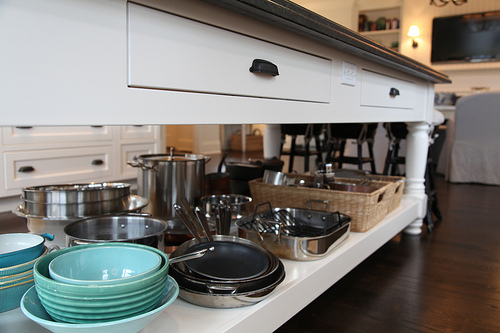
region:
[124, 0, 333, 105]
White drawer with black drawer pull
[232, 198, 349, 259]
Stainless steel roasting pan with handles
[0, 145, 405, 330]
White shelf with many different kitchen items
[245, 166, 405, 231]
Side by side wicker baskets with hand holes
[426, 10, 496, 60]
Black flat screen TV above a shelf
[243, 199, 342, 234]
Black roasting pan rack with a handle on each side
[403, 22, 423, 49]
Wall sconce with a white shade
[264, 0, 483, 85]
Side of a gray granite counter top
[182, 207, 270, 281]
Skillet with a metal handle and black non-stick coating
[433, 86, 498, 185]
Chair with a white cloth chair cover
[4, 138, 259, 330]
assortment of cookware on shelf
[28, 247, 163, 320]
a couple of light blue bowls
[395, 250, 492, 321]
wooden floor in room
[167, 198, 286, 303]
several pans stacked on each other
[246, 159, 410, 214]
wicker baskets filled with items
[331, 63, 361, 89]
electrical outlet for appliances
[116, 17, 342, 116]
drawer on shelf in room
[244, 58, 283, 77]
handle to drawer on shelf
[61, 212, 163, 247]
an open pot in dishware set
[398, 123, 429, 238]
leg to shelf in room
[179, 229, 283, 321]
pans on a white shelf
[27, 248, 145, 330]
blue bowls on a white shelf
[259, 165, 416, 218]
wicker baskets on a white shelf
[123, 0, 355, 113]
drawer with black handle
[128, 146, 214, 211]
steel stock pot on the white shelf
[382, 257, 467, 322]
dark brown wood flooring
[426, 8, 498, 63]
flat screen tv on the wall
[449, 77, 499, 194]
chair in front of the tv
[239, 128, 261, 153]
basket on the floor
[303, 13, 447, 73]
edge of counter top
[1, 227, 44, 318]
Part of stack of bowls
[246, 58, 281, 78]
Handle for drawer piull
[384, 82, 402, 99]
Handle for drawer pull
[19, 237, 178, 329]
Stack of serving bowls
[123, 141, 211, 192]
Part of stainless steel pot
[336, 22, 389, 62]
Part pf counter top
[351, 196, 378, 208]
Part pf storage basket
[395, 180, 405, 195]
Part of storage basket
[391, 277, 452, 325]
Brown wooden floor overing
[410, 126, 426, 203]
White leg on center counter storage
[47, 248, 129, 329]
Blue bowls inside of white bowl.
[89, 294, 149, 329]
White bowl sitting on counter top.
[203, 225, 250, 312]
Stack of silver pans on counter.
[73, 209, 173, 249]
Silver pot on counter top.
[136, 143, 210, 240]
Large silver pot on counter top.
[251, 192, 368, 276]
Silver pan on top of counter.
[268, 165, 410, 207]
Brown baskets on counter top.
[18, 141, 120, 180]
White drawer in background.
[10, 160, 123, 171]
Black handles on white cupboard.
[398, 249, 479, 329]
Brown wood floors in room.